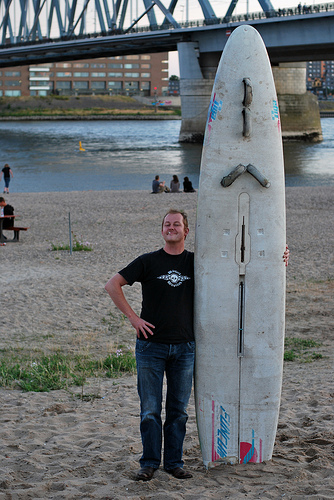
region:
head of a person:
[151, 195, 195, 251]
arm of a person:
[104, 264, 159, 336]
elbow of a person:
[101, 278, 124, 298]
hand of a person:
[134, 306, 159, 340]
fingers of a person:
[135, 306, 165, 343]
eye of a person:
[163, 216, 171, 229]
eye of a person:
[171, 215, 190, 230]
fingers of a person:
[281, 243, 300, 274]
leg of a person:
[114, 353, 176, 457]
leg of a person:
[156, 365, 216, 459]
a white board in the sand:
[193, 22, 286, 468]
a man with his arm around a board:
[102, 208, 289, 479]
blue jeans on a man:
[135, 336, 195, 464]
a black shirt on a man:
[119, 247, 197, 339]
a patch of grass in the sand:
[49, 241, 92, 254]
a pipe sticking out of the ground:
[66, 211, 74, 253]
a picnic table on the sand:
[0, 214, 29, 244]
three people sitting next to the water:
[148, 169, 198, 192]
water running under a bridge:
[0, 112, 333, 195]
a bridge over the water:
[0, 0, 333, 59]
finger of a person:
[137, 327, 157, 338]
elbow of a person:
[93, 278, 113, 293]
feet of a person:
[137, 454, 164, 487]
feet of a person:
[169, 454, 203, 489]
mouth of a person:
[165, 225, 183, 239]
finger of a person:
[266, 239, 298, 275]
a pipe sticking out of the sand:
[65, 209, 79, 255]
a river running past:
[1, 115, 333, 187]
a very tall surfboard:
[188, 22, 324, 468]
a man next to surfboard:
[63, 188, 259, 497]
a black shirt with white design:
[114, 235, 214, 346]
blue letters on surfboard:
[200, 377, 259, 470]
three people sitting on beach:
[127, 162, 209, 215]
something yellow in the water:
[73, 124, 111, 166]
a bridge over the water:
[7, 2, 332, 54]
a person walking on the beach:
[3, 157, 20, 200]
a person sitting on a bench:
[1, 195, 30, 246]